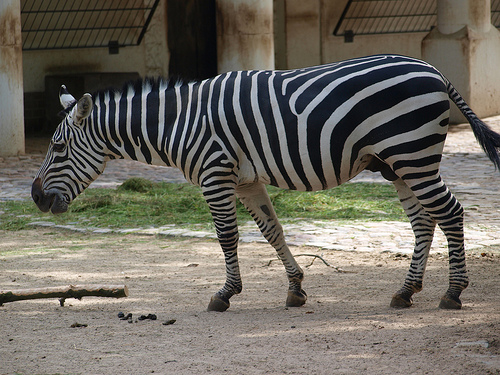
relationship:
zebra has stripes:
[24, 44, 500, 315] [173, 83, 334, 162]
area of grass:
[2, 52, 496, 365] [92, 193, 199, 225]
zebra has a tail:
[24, 44, 500, 315] [422, 53, 500, 176]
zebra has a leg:
[24, 44, 500, 315] [179, 157, 250, 321]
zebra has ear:
[24, 44, 500, 315] [67, 88, 98, 127]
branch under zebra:
[0, 269, 156, 311] [24, 44, 500, 315]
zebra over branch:
[24, 44, 500, 315] [0, 269, 156, 311]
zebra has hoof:
[24, 44, 500, 315] [203, 292, 238, 316]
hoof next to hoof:
[203, 292, 238, 316] [282, 278, 323, 313]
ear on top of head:
[67, 88, 98, 127] [11, 78, 120, 209]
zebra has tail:
[24, 44, 500, 315] [422, 53, 500, 176]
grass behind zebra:
[92, 193, 199, 225] [24, 44, 500, 315]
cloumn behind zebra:
[204, 0, 279, 169] [24, 44, 500, 315]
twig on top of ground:
[265, 251, 348, 285] [1, 159, 499, 368]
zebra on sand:
[24, 44, 500, 315] [5, 230, 496, 368]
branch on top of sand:
[0, 269, 156, 311] [5, 230, 496, 368]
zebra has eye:
[24, 44, 500, 315] [49, 141, 73, 162]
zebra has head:
[24, 44, 500, 315] [11, 78, 120, 209]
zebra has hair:
[24, 44, 500, 315] [71, 76, 196, 103]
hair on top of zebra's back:
[71, 71, 208, 109] [59, 73, 286, 103]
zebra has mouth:
[24, 44, 500, 315] [19, 176, 83, 217]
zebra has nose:
[24, 44, 500, 315] [24, 182, 54, 214]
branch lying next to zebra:
[0, 269, 156, 311] [24, 44, 500, 315]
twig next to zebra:
[265, 251, 348, 285] [24, 44, 500, 315]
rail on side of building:
[6, 0, 171, 56] [2, 0, 498, 155]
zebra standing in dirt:
[24, 44, 500, 315] [2, 230, 493, 370]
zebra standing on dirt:
[24, 44, 500, 315] [2, 230, 493, 370]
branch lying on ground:
[0, 269, 156, 311] [1, 159, 499, 368]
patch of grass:
[90, 186, 206, 225] [92, 193, 199, 225]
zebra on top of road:
[24, 44, 500, 315] [6, 221, 500, 335]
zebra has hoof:
[24, 44, 500, 315] [282, 278, 323, 313]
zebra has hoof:
[24, 44, 500, 315] [379, 284, 428, 318]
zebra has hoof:
[24, 44, 500, 315] [430, 288, 470, 315]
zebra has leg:
[24, 44, 500, 315] [179, 157, 250, 321]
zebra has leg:
[24, 44, 500, 315] [216, 180, 321, 310]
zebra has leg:
[24, 44, 500, 315] [372, 169, 442, 316]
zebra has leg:
[24, 44, 500, 315] [392, 155, 481, 308]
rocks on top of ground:
[87, 302, 196, 334] [1, 159, 499, 368]